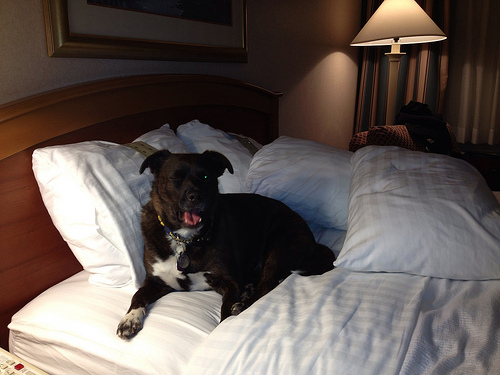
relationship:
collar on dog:
[152, 211, 219, 243] [117, 149, 337, 341]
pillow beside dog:
[31, 124, 194, 296] [117, 149, 337, 341]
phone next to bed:
[0, 346, 48, 373] [8, 117, 499, 373]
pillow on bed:
[31, 124, 194, 296] [8, 117, 499, 373]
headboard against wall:
[0, 70, 284, 353] [1, 1, 359, 149]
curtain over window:
[351, 1, 447, 132] [355, 1, 498, 143]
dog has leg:
[117, 149, 337, 341] [113, 278, 178, 341]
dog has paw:
[117, 149, 337, 341] [115, 306, 147, 340]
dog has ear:
[117, 149, 337, 341] [203, 149, 234, 177]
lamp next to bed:
[350, 1, 447, 124] [8, 117, 499, 373]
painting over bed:
[43, 1, 251, 67] [8, 117, 499, 373]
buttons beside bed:
[2, 361, 27, 374] [8, 117, 499, 373]